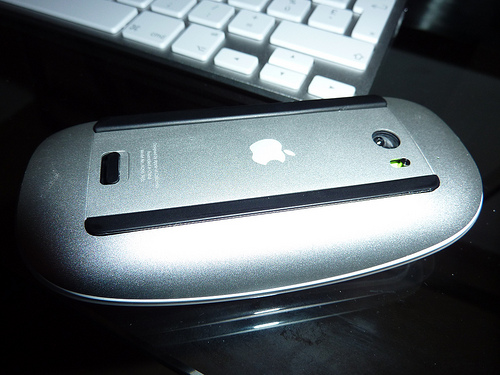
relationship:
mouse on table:
[19, 93, 486, 308] [0, 0, 499, 374]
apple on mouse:
[244, 132, 294, 167] [4, 80, 483, 312]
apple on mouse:
[249, 138, 294, 164] [19, 93, 486, 308]